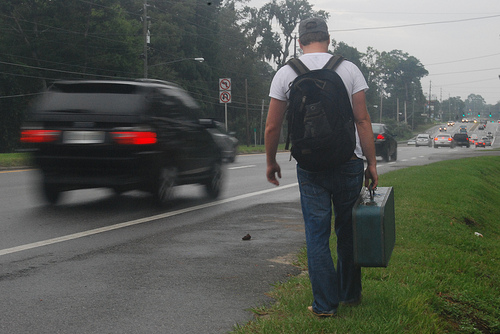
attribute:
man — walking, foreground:
[282, 27, 405, 254]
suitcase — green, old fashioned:
[355, 191, 396, 272]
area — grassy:
[367, 169, 492, 333]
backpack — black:
[291, 64, 351, 168]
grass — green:
[319, 147, 500, 310]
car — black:
[32, 89, 212, 191]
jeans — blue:
[303, 169, 372, 310]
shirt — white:
[262, 61, 359, 105]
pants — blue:
[293, 158, 377, 287]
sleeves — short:
[342, 67, 374, 88]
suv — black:
[44, 83, 249, 204]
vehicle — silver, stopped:
[193, 118, 255, 161]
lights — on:
[98, 129, 156, 143]